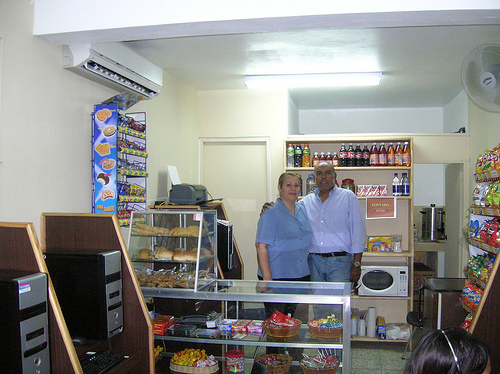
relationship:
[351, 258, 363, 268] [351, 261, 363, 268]
watch on watch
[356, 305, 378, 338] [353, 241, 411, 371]
cups stacked on shelf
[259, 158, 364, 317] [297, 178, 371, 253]
man wearing shirt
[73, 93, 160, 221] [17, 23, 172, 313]
rack on wall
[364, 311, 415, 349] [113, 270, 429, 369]
bowls in cabinet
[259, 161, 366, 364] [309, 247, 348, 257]
man wearing belt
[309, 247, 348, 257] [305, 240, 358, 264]
belt around waist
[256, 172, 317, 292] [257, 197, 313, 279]
woman wearing shirt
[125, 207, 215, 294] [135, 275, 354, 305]
case on counter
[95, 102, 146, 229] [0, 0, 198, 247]
shelf against painted wall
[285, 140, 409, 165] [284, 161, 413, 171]
bottles on shelf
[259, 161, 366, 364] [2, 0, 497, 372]
man in cafe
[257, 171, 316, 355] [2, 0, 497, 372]
woman in cafe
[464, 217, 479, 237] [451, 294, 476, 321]
chip beside shelf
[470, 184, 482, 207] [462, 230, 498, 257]
chip beside shelf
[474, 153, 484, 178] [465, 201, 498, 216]
chip beside shelf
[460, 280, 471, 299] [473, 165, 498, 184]
chip beside shelf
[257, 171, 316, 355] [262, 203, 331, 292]
woman wearing shirt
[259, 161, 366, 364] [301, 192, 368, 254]
man wearing shirt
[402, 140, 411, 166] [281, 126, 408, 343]
driinks on shelf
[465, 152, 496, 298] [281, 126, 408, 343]
driinks on shelf